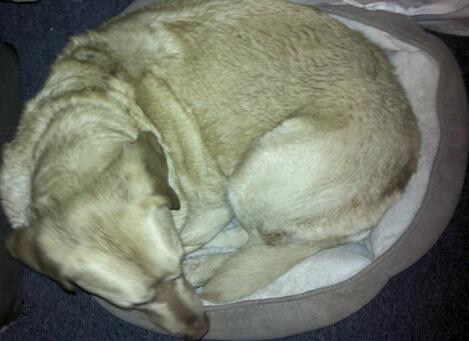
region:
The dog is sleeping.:
[0, 0, 468, 338]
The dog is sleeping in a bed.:
[74, 5, 467, 339]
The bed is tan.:
[283, 229, 415, 338]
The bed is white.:
[369, 16, 449, 105]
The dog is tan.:
[3, 1, 415, 336]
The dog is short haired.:
[5, 6, 421, 337]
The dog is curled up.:
[2, 1, 423, 338]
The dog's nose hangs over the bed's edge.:
[87, 278, 220, 338]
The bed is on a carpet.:
[305, 244, 467, 339]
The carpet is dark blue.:
[320, 253, 467, 338]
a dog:
[14, 11, 437, 338]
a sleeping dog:
[10, 0, 453, 338]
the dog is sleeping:
[15, 6, 423, 336]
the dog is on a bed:
[11, 4, 467, 339]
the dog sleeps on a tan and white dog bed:
[14, 3, 463, 334]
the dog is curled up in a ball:
[23, 2, 443, 337]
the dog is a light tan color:
[16, 4, 452, 332]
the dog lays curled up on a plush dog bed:
[19, 2, 446, 330]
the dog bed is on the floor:
[9, 7, 465, 335]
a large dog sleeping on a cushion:
[20, 4, 443, 336]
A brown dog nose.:
[152, 308, 228, 336]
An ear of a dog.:
[101, 124, 193, 229]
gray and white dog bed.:
[195, 175, 463, 333]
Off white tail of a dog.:
[198, 226, 340, 316]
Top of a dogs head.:
[30, 134, 192, 281]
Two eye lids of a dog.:
[95, 251, 208, 322]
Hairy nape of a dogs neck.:
[2, 104, 146, 216]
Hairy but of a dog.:
[263, 117, 440, 218]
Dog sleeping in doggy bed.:
[17, 10, 449, 323]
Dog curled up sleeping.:
[50, 98, 454, 323]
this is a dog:
[8, 7, 363, 311]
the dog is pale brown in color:
[8, 4, 376, 326]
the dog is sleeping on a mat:
[310, 254, 356, 319]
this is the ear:
[129, 127, 171, 216]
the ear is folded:
[142, 136, 180, 215]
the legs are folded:
[196, 211, 282, 297]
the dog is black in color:
[194, 314, 208, 332]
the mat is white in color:
[308, 253, 346, 277]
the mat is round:
[274, 271, 351, 317]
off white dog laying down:
[19, 23, 408, 337]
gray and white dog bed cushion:
[321, 10, 444, 338]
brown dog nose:
[184, 315, 216, 337]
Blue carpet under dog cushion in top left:
[3, 5, 71, 63]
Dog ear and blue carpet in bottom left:
[3, 256, 105, 338]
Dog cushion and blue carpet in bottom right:
[348, 249, 465, 339]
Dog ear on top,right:
[125, 133, 183, 213]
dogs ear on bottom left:
[5, 229, 78, 293]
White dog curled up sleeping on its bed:
[14, 22, 460, 332]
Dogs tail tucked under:
[199, 226, 344, 303]